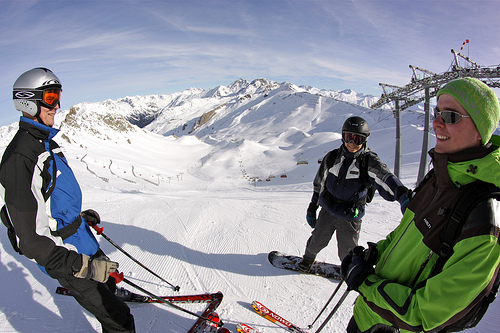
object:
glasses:
[434, 106, 469, 123]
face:
[431, 94, 473, 153]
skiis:
[249, 299, 307, 333]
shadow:
[97, 221, 300, 276]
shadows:
[0, 258, 62, 333]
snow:
[202, 212, 251, 244]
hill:
[202, 84, 235, 98]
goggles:
[40, 87, 63, 109]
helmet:
[12, 67, 62, 118]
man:
[0, 67, 135, 333]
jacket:
[351, 136, 500, 333]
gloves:
[342, 245, 376, 291]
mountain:
[228, 78, 251, 91]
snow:
[201, 158, 231, 174]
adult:
[337, 75, 500, 333]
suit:
[346, 135, 500, 333]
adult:
[297, 115, 413, 272]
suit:
[305, 147, 409, 261]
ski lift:
[369, 65, 500, 115]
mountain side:
[205, 93, 339, 145]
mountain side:
[62, 107, 173, 170]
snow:
[102, 144, 148, 156]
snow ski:
[182, 291, 225, 333]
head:
[11, 67, 63, 126]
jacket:
[0, 118, 101, 280]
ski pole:
[93, 225, 181, 291]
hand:
[59, 220, 133, 316]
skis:
[268, 250, 340, 278]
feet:
[297, 257, 314, 272]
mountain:
[60, 98, 136, 148]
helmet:
[341, 116, 370, 143]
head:
[341, 116, 370, 152]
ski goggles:
[342, 131, 367, 145]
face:
[41, 90, 62, 125]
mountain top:
[0, 188, 499, 333]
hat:
[435, 75, 500, 145]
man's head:
[431, 77, 500, 154]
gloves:
[74, 253, 120, 285]